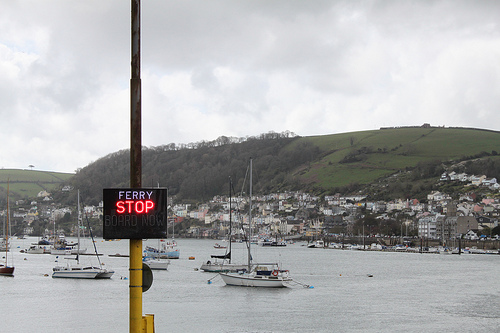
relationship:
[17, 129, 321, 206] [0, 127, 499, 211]
trees are on hill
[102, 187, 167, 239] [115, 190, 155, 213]
sign has text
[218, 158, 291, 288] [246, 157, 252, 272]
sailboat has a tall mast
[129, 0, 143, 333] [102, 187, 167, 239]
pole has a sign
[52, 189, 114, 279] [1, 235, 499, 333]
sailboat are in ocean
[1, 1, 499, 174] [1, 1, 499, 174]
sky has clouds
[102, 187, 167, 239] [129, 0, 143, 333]
sign on pole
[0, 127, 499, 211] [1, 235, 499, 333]
hill above ocean